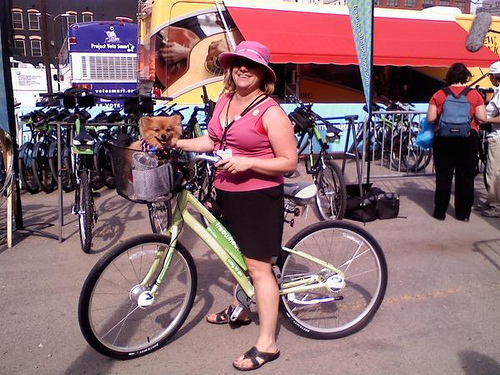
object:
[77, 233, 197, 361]
tire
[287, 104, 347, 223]
bicycle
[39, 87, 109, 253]
bicycle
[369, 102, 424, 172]
bicycle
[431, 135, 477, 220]
black pants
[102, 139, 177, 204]
basket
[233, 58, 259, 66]
sunglasses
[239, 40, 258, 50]
pink hat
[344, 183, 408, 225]
bag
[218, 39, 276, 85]
hat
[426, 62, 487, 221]
person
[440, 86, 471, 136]
backpack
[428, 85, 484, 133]
shirt sleeve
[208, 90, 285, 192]
pink shirt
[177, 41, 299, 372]
lady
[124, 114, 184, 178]
dog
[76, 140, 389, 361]
bicycle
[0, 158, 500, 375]
ground